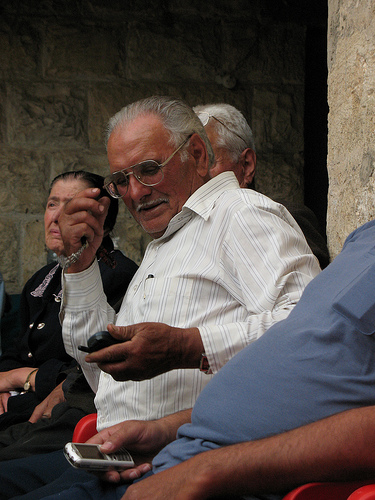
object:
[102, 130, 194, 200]
eyeglasses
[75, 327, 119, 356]
phone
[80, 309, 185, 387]
hand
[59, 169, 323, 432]
shirt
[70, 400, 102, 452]
seat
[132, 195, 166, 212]
mustache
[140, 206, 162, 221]
lip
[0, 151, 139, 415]
woman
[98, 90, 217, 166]
hair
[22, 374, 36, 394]
watch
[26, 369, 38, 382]
band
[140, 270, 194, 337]
pocket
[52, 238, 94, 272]
watch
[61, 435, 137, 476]
phone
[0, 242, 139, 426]
shirt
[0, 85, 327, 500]
man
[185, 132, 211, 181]
ear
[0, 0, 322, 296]
wall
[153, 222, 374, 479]
shirt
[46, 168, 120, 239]
hair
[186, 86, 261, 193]
head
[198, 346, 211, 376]
watch